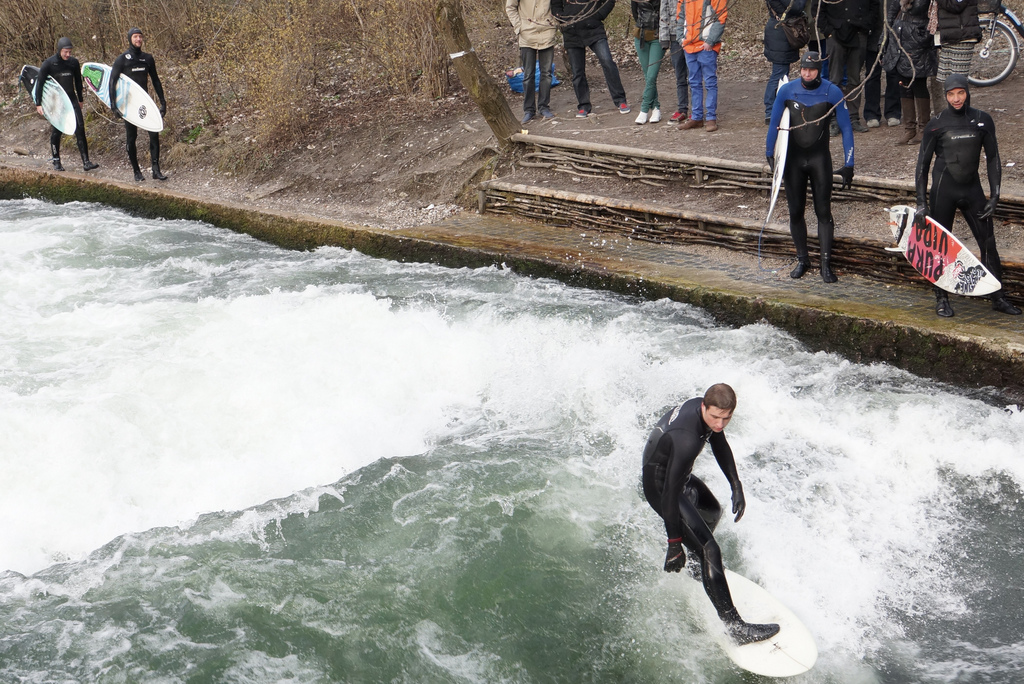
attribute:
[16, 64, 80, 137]
surfboard — white, black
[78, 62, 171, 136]
surfboard — white, green, black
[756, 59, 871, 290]
wetsuit — blue, black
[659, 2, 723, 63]
jacket — orange, gray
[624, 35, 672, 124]
shoes — white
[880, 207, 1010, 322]
surfboard — white, black, red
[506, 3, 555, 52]
jacket — tan